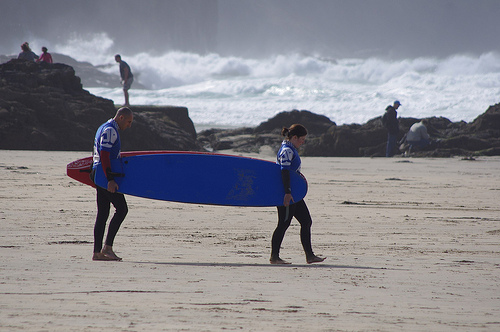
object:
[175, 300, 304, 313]
footprints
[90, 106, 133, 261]
man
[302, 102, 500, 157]
rocks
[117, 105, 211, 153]
rocks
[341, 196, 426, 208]
waves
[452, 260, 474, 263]
waves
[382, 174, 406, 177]
waves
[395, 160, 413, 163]
waves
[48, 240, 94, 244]
tracks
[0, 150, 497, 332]
beach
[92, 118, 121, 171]
tshirt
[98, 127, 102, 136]
blue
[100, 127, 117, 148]
white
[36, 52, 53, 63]
blouse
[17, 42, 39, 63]
person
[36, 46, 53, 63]
person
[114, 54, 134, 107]
person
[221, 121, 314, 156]
waves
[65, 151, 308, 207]
surfboard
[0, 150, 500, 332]
floor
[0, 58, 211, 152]
rock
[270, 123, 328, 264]
person